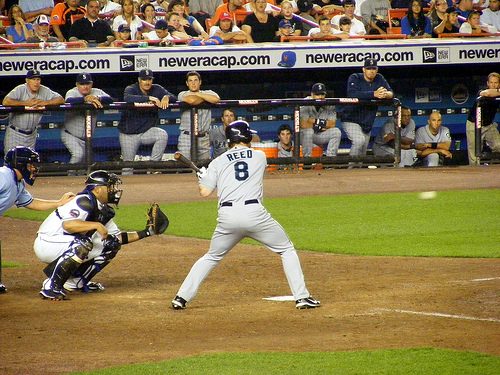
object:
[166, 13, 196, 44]
spectator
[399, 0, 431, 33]
spectator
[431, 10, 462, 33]
spectator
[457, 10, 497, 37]
spectator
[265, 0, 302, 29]
spectator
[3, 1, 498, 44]
fans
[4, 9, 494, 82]
stands